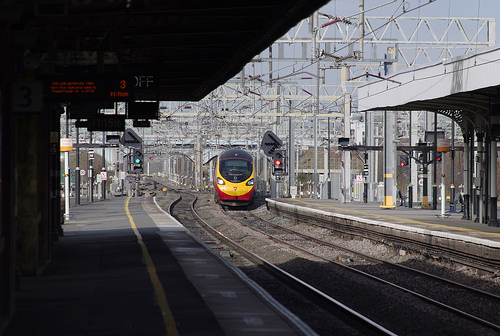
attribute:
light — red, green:
[265, 144, 288, 169]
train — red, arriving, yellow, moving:
[209, 148, 251, 205]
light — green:
[132, 155, 142, 165]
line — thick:
[119, 194, 182, 335]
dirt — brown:
[201, 217, 240, 268]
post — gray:
[62, 145, 75, 225]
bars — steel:
[271, 23, 434, 73]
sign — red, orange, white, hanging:
[56, 136, 86, 156]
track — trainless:
[163, 188, 213, 234]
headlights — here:
[218, 173, 259, 190]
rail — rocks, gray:
[304, 226, 400, 265]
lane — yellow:
[121, 204, 141, 236]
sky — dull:
[328, 34, 419, 53]